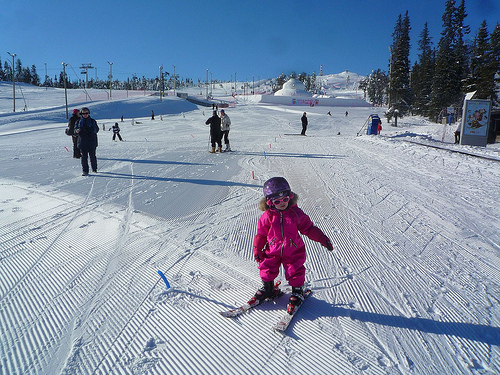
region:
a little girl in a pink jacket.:
[152, 173, 369, 333]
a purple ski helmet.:
[260, 167, 312, 201]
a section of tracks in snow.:
[0, 177, 216, 373]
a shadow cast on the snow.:
[266, 294, 498, 346]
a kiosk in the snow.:
[444, 82, 492, 152]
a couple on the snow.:
[200, 102, 249, 167]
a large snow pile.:
[272, 61, 326, 101]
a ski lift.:
[61, 43, 100, 82]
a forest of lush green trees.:
[340, 0, 498, 130]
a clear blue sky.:
[0, 0, 498, 82]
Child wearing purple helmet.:
[258, 176, 296, 206]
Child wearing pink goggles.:
[263, 192, 305, 210]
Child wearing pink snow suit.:
[260, 212, 295, 329]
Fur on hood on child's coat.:
[249, 194, 291, 227]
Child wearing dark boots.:
[249, 278, 306, 319]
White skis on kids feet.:
[223, 265, 298, 372]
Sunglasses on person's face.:
[73, 100, 105, 131]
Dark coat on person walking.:
[58, 127, 113, 152]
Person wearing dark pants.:
[71, 149, 133, 203]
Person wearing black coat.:
[198, 105, 235, 168]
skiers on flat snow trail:
[35, 75, 460, 340]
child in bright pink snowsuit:
[207, 167, 352, 333]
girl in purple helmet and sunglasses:
[251, 175, 307, 220]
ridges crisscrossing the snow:
[335, 145, 472, 360]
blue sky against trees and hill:
[5, 35, 365, 112]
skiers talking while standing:
[195, 90, 245, 166]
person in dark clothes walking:
[66, 97, 106, 177]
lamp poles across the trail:
[5, 25, 340, 120]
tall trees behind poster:
[446, 72, 491, 147]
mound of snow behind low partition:
[247, 58, 373, 110]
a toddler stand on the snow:
[239, 171, 342, 316]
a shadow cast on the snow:
[317, 296, 498, 347]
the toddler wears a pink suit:
[240, 170, 342, 299]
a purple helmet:
[259, 174, 295, 197]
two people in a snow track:
[199, 99, 241, 159]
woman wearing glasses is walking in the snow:
[67, 105, 105, 182]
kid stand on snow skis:
[216, 169, 345, 339]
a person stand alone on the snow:
[296, 106, 314, 139]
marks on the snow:
[9, 208, 182, 368]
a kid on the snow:
[105, 119, 127, 144]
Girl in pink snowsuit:
[253, 175, 335, 304]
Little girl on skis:
[215, 170, 340, 333]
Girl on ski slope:
[219, 176, 336, 337]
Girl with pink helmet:
[257, 171, 299, 213]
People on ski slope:
[206, 103, 239, 157]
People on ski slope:
[62, 103, 112, 172]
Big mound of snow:
[266, 74, 320, 114]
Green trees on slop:
[364, 3, 494, 120]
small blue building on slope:
[359, 111, 387, 136]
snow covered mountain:
[5, 63, 497, 370]